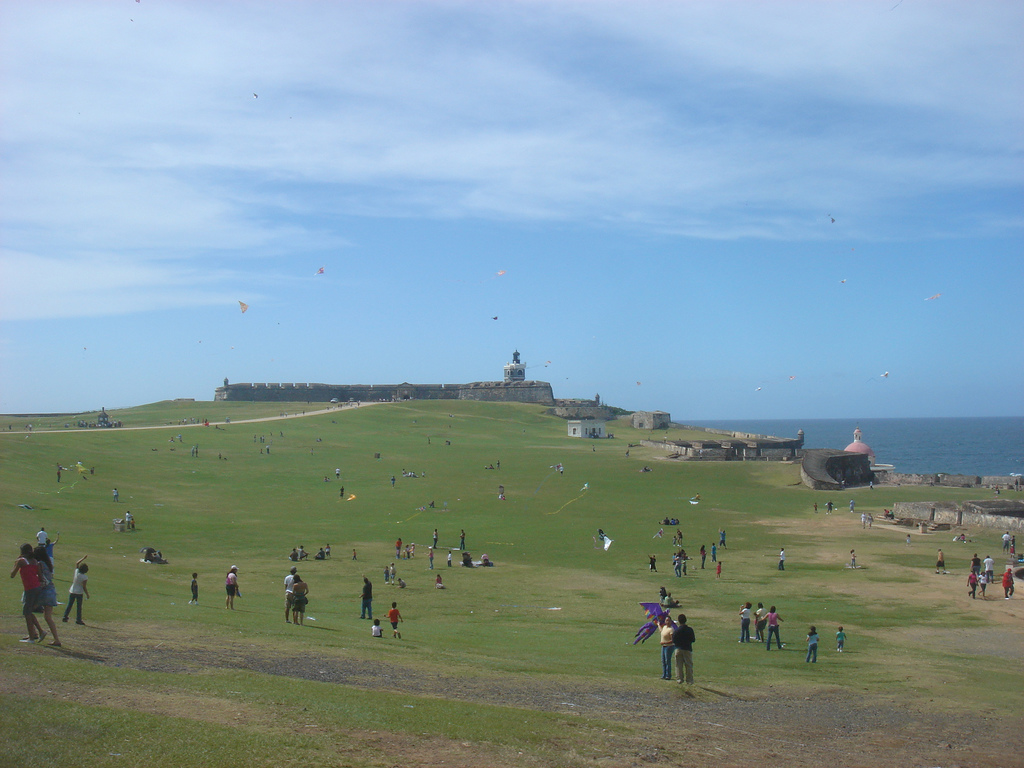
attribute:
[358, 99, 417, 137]
clouds — white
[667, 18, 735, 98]
clouds — white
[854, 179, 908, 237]
clouds — white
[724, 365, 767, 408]
clouds — white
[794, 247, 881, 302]
clouds — white 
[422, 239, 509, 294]
kites — white 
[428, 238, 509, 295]
clouds — white 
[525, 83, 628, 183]
clouds — white 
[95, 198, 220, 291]
clouds — white 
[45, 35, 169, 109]
kites — white 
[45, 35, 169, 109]
clouds — white 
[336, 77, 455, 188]
clouds — white 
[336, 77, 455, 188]
kites — white 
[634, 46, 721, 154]
kites — white 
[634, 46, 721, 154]
clouds — white 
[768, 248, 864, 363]
clouds — white 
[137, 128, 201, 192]
clouds — white 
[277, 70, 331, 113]
clouds — white 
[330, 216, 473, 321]
clouds — white 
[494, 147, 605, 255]
clouds — white 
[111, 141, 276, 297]
clouds — white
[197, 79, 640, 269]
clouds — white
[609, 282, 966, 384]
sky — blue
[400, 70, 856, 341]
sky — blue 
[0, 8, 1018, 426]
sky — blue